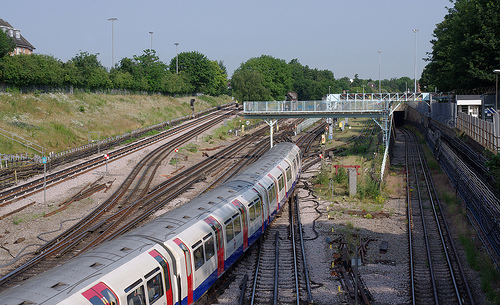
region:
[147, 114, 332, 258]
Train on the tracks.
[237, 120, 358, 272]
Tracks with train on it.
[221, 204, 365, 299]
Rail road tracks.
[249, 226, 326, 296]
Gravel on the railroad tracks.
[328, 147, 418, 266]
Grass on the ground.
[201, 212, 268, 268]
Windows on the train.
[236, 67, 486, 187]
Bridge over the tracks.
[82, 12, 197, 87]
Lights in the background.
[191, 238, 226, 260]
windows on the train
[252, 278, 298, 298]
the train tracks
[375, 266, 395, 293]
small rocks on the ground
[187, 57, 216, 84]
a green bush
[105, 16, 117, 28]
the street light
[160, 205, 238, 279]
a train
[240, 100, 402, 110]
an overpass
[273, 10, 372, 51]
the sky is clear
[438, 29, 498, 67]
the tree leaves are green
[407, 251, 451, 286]
the train tracks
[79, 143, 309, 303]
A long grey train travelling along the train tracks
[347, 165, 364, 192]
A small grey pole by the train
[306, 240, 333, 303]
Rocks littering the side if the train tracks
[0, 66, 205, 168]
A sloping hill to the left of the train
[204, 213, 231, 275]
Red doors on the train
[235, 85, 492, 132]
A small bridge over the train tracks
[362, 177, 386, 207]
Green vegetation growing by the train tracks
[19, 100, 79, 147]
Short green grass growing on the hill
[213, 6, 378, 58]
A clear blue sky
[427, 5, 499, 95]
A thick green tree to the right of the train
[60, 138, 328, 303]
gray train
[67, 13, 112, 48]
whiate clouds in blue sky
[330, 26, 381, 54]
whiate clouds in blue sky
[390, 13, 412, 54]
whiate clouds in blue sky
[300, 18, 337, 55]
whiate clouds in blue sky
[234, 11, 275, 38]
whiate clouds in blue sky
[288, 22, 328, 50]
whiate clouds in blue sky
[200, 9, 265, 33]
whiate clouds in blue sky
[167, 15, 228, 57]
whiate clouds in blue sky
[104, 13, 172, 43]
whiate clouds in blue sky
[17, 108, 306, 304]
red blue silver train on tracks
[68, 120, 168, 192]
train tracks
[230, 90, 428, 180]
bridge above train tracks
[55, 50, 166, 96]
several trees with green leafs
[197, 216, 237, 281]
red door of train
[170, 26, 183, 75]
pole with light outside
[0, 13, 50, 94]
house on hill behind trees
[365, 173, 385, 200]
several bushes of weeds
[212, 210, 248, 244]
window of side of train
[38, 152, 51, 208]
sign and post in ground